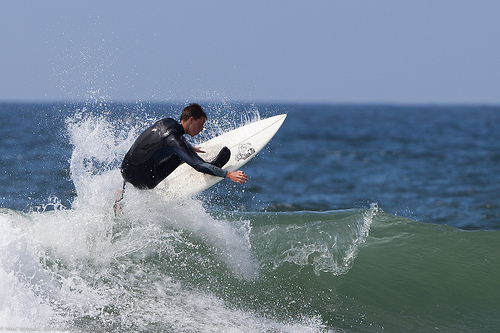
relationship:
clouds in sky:
[6, 7, 500, 58] [1, 2, 500, 104]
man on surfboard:
[110, 103, 249, 204] [63, 104, 294, 241]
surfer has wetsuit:
[110, 103, 249, 204] [115, 119, 222, 195]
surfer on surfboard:
[110, 103, 249, 204] [63, 104, 294, 241]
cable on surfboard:
[113, 179, 131, 216] [63, 104, 294, 241]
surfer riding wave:
[110, 103, 249, 204] [0, 212, 499, 333]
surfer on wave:
[110, 103, 249, 204] [0, 212, 499, 333]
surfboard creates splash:
[63, 104, 294, 241] [60, 115, 152, 275]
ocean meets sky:
[1, 103, 499, 333] [1, 2, 500, 104]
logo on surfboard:
[233, 140, 259, 164] [63, 104, 294, 241]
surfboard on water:
[63, 104, 294, 241] [1, 103, 499, 333]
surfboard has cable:
[63, 104, 294, 241] [113, 179, 131, 216]